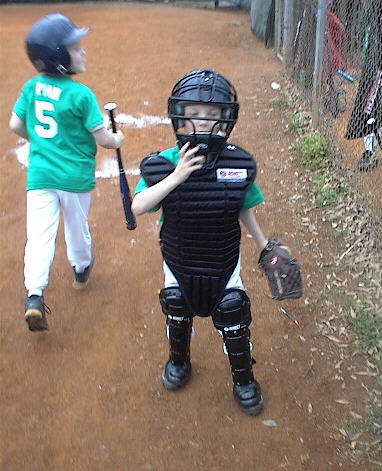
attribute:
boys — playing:
[10, 12, 315, 419]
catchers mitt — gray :
[254, 236, 305, 305]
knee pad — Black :
[209, 290, 249, 332]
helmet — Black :
[165, 73, 236, 107]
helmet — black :
[9, 7, 113, 104]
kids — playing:
[13, 12, 318, 354]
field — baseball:
[7, 0, 362, 457]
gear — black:
[138, 69, 255, 385]